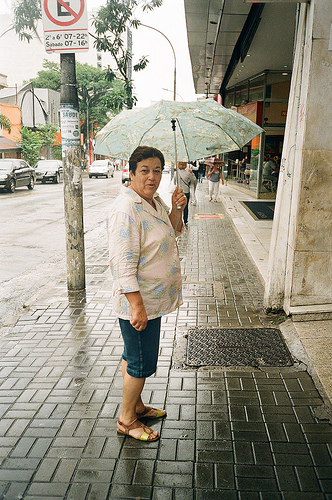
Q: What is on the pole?
A: A sign.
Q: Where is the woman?
A: On the sidewalk.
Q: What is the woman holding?
A: An umbrella.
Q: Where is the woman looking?
A: At the camera.